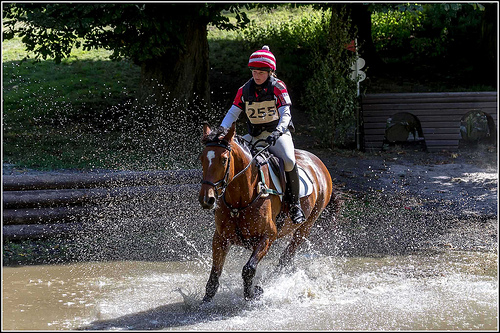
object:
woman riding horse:
[185, 44, 352, 303]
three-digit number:
[248, 106, 277, 119]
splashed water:
[269, 254, 345, 302]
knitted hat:
[247, 44, 278, 71]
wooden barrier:
[360, 89, 498, 152]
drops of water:
[142, 116, 176, 134]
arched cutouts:
[384, 111, 428, 153]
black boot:
[284, 159, 314, 225]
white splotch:
[206, 150, 217, 169]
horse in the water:
[187, 122, 337, 308]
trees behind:
[1, 0, 230, 106]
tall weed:
[323, 40, 356, 142]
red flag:
[340, 39, 356, 52]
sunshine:
[218, 2, 322, 45]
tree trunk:
[134, 25, 214, 112]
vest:
[238, 78, 279, 136]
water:
[0, 154, 499, 332]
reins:
[226, 142, 270, 185]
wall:
[352, 88, 483, 155]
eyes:
[221, 158, 228, 165]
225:
[247, 106, 276, 119]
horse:
[194, 124, 340, 305]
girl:
[220, 46, 306, 222]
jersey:
[217, 72, 297, 141]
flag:
[333, 36, 360, 146]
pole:
[353, 39, 361, 151]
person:
[212, 40, 303, 229]